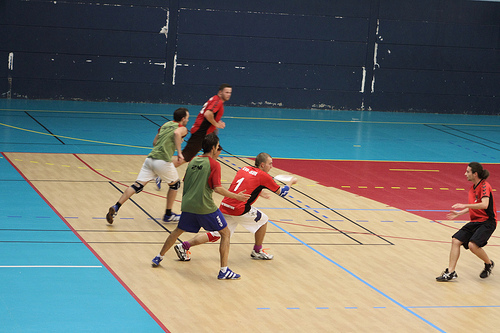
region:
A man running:
[438, 159, 495, 291]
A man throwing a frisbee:
[233, 150, 298, 266]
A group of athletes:
[104, 83, 296, 283]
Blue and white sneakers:
[219, 269, 244, 284]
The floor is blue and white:
[371, 113, 463, 198]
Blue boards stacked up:
[275, 9, 453, 108]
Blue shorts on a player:
[181, 210, 226, 232]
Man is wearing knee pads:
[127, 181, 147, 193]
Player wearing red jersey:
[468, 184, 493, 228]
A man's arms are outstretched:
[440, 197, 497, 217]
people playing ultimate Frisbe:
[72, 35, 499, 305]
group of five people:
[86, 58, 499, 304]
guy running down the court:
[169, 76, 249, 164]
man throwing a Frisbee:
[187, 142, 306, 264]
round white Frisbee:
[275, 169, 304, 186]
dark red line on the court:
[7, 151, 178, 332]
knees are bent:
[446, 229, 486, 261]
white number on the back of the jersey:
[230, 170, 249, 198]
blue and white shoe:
[216, 266, 244, 281]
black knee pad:
[125, 178, 150, 194]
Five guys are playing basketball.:
[107, 83, 499, 283]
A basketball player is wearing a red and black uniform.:
[435, 160, 498, 285]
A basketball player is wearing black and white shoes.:
[433, 258, 495, 283]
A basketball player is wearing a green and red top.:
[176, 150, 224, 215]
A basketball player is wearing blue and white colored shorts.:
[176, 207, 228, 235]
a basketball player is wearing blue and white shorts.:
[149, 255, 241, 280]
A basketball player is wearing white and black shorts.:
[210, 202, 268, 235]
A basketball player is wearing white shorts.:
[134, 153, 181, 186]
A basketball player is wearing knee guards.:
[128, 174, 180, 194]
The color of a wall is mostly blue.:
[1, 1, 498, 111]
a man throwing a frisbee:
[172, 150, 294, 260]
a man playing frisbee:
[150, 134, 241, 283]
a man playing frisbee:
[103, 105, 192, 227]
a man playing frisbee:
[180, 82, 232, 165]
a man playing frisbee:
[432, 161, 498, 288]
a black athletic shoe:
[435, 268, 454, 283]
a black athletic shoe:
[477, 261, 492, 279]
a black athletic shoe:
[105, 204, 112, 226]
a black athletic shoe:
[161, 210, 179, 222]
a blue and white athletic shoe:
[215, 266, 239, 280]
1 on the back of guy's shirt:
[219, 173, 253, 204]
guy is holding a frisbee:
[269, 170, 300, 190]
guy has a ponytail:
[464, 155, 487, 185]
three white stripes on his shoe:
[203, 267, 244, 283]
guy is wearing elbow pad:
[269, 182, 300, 201]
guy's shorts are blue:
[158, 212, 256, 237]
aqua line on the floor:
[343, 255, 389, 301]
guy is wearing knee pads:
[119, 172, 186, 204]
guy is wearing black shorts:
[464, 221, 484, 246]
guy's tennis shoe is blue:
[216, 259, 237, 285]